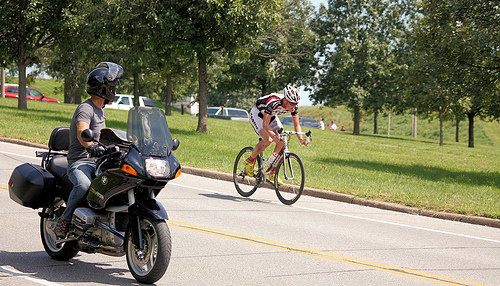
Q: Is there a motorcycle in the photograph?
A: Yes, there is a motorcycle.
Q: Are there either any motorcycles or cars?
A: Yes, there is a motorcycle.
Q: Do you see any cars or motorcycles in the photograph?
A: Yes, there is a motorcycle.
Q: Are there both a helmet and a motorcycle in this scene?
A: Yes, there are both a motorcycle and a helmet.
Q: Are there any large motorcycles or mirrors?
A: Yes, there is a large motorcycle.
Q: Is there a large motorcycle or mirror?
A: Yes, there is a large motorcycle.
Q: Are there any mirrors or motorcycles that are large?
A: Yes, the motorcycle is large.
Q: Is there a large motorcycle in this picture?
A: Yes, there is a large motorcycle.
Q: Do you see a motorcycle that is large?
A: Yes, there is a motorcycle that is large.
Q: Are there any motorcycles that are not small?
A: Yes, there is a large motorcycle.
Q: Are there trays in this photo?
A: No, there are no trays.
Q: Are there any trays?
A: No, there are no trays.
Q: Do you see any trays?
A: No, there are no trays.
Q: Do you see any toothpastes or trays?
A: No, there are no trays or toothpastes.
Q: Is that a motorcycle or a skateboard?
A: That is a motorcycle.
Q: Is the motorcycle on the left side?
A: Yes, the motorcycle is on the left of the image.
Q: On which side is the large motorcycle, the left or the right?
A: The motorcycle is on the left of the image.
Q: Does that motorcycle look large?
A: Yes, the motorcycle is large.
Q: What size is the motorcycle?
A: The motorcycle is large.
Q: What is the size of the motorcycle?
A: The motorcycle is large.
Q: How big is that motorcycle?
A: The motorcycle is large.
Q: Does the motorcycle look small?
A: No, the motorcycle is large.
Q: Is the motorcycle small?
A: No, the motorcycle is large.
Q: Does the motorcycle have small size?
A: No, the motorcycle is large.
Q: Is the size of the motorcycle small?
A: No, the motorcycle is large.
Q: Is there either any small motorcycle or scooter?
A: No, there is a motorcycle but it is large.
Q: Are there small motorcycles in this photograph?
A: No, there is a motorcycle but it is large.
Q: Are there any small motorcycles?
A: No, there is a motorcycle but it is large.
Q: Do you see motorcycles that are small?
A: No, there is a motorcycle but it is large.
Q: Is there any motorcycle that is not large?
A: No, there is a motorcycle but it is large.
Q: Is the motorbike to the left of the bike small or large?
A: The motorcycle is large.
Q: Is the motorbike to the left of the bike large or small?
A: The motorcycle is large.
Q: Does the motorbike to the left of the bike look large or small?
A: The motorcycle is large.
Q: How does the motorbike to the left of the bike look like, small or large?
A: The motorcycle is large.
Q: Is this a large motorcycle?
A: Yes, this is a large motorcycle.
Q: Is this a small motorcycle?
A: No, this is a large motorcycle.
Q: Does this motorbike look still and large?
A: Yes, the motorbike is still and large.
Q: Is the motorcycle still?
A: Yes, the motorcycle is still.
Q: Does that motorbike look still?
A: Yes, the motorbike is still.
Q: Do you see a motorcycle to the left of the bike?
A: Yes, there is a motorcycle to the left of the bike.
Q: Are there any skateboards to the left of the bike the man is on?
A: No, there is a motorcycle to the left of the bike.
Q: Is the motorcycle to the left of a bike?
A: Yes, the motorcycle is to the left of a bike.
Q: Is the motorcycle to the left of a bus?
A: No, the motorcycle is to the left of a bike.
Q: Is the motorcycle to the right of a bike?
A: No, the motorcycle is to the left of a bike.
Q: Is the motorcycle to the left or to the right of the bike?
A: The motorcycle is to the left of the bike.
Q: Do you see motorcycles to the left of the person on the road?
A: Yes, there is a motorcycle to the left of the person.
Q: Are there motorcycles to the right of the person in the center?
A: No, the motorcycle is to the left of the person.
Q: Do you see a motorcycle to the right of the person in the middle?
A: No, the motorcycle is to the left of the person.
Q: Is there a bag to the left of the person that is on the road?
A: No, there is a motorcycle to the left of the person.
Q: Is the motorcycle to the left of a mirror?
A: No, the motorcycle is to the left of the person.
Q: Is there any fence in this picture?
A: No, there are no fences.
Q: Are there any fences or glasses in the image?
A: No, there are no fences or glasses.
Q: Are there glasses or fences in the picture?
A: No, there are no fences or glasses.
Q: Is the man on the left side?
A: Yes, the man is on the left of the image.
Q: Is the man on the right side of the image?
A: No, the man is on the left of the image.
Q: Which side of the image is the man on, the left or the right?
A: The man is on the left of the image.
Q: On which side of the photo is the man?
A: The man is on the left of the image.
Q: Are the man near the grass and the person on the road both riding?
A: Yes, both the man and the person are riding.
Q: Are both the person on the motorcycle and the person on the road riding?
A: Yes, both the man and the person are riding.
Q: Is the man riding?
A: Yes, the man is riding.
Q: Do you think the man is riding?
A: Yes, the man is riding.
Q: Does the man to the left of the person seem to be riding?
A: Yes, the man is riding.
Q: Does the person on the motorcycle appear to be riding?
A: Yes, the man is riding.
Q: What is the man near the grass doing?
A: The man is riding.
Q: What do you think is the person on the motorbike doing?
A: The man is riding.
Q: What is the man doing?
A: The man is riding.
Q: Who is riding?
A: The man is riding.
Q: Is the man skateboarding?
A: No, the man is riding.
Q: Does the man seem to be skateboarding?
A: No, the man is riding.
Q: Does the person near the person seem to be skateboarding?
A: No, the man is riding.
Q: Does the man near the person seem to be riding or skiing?
A: The man is riding.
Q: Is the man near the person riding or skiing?
A: The man is riding.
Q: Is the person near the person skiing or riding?
A: The man is riding.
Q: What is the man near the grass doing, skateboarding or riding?
A: The man is riding.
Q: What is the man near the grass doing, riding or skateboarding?
A: The man is riding.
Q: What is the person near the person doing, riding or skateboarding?
A: The man is riding.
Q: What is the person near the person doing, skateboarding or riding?
A: The man is riding.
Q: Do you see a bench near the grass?
A: No, there is a man near the grass.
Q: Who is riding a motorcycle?
A: The man is riding a motorcycle.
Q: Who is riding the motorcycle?
A: The man is riding a motorcycle.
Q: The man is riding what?
A: The man is riding a motorcycle.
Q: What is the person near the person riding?
A: The man is riding a motorcycle.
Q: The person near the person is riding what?
A: The man is riding a motorcycle.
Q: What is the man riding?
A: The man is riding a motorcycle.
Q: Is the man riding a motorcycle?
A: Yes, the man is riding a motorcycle.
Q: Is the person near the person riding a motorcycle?
A: Yes, the man is riding a motorcycle.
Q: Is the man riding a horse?
A: No, the man is riding a motorcycle.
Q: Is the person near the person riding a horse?
A: No, the man is riding a motorcycle.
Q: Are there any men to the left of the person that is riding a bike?
A: Yes, there is a man to the left of the person.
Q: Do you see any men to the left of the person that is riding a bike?
A: Yes, there is a man to the left of the person.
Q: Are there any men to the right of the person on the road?
A: No, the man is to the left of the person.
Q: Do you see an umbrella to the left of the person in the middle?
A: No, there is a man to the left of the person.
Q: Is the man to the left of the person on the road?
A: Yes, the man is to the left of the person.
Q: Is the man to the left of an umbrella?
A: No, the man is to the left of the person.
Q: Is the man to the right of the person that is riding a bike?
A: No, the man is to the left of the person.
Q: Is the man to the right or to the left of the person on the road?
A: The man is to the left of the person.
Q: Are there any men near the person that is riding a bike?
A: Yes, there is a man near the person.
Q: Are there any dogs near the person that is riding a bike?
A: No, there is a man near the person.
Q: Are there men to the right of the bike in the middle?
A: No, the man is to the left of the bike.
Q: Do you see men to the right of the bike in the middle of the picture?
A: No, the man is to the left of the bike.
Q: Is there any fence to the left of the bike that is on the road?
A: No, there is a man to the left of the bike.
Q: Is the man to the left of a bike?
A: Yes, the man is to the left of a bike.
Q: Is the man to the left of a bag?
A: No, the man is to the left of a bike.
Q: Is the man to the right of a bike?
A: No, the man is to the left of a bike.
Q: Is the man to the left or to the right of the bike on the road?
A: The man is to the left of the bike.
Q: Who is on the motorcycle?
A: The man is on the motorcycle.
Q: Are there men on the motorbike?
A: Yes, there is a man on the motorbike.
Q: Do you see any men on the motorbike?
A: Yes, there is a man on the motorbike.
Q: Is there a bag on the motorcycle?
A: No, there is a man on the motorcycle.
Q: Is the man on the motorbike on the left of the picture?
A: Yes, the man is on the motorbike.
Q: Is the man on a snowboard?
A: No, the man is on the motorbike.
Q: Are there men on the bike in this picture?
A: Yes, there is a man on the bike.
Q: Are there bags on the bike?
A: No, there is a man on the bike.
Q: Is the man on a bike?
A: Yes, the man is on a bike.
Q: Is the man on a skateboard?
A: No, the man is on a bike.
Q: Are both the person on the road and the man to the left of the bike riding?
A: Yes, both the person and the man are riding.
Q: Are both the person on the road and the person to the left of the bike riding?
A: Yes, both the person and the man are riding.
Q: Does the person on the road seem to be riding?
A: Yes, the person is riding.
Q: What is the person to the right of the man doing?
A: The person is riding.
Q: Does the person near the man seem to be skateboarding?
A: No, the person is riding.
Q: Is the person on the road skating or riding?
A: The person is riding.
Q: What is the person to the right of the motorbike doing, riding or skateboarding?
A: The person is riding.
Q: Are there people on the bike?
A: Yes, there is a person on the bike.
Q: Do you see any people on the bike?
A: Yes, there is a person on the bike.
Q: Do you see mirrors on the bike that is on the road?
A: No, there is a person on the bike.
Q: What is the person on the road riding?
A: The person is riding a bike.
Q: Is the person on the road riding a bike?
A: Yes, the person is riding a bike.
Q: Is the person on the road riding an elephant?
A: No, the person is riding a bike.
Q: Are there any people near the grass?
A: Yes, there is a person near the grass.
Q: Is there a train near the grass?
A: No, there is a person near the grass.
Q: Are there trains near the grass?
A: No, there is a person near the grass.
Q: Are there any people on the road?
A: Yes, there is a person on the road.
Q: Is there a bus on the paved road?
A: No, there is a person on the road.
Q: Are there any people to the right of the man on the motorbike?
A: Yes, there is a person to the right of the man.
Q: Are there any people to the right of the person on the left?
A: Yes, there is a person to the right of the man.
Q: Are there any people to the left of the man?
A: No, the person is to the right of the man.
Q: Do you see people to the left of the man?
A: No, the person is to the right of the man.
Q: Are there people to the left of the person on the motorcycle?
A: No, the person is to the right of the man.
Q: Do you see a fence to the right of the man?
A: No, there is a person to the right of the man.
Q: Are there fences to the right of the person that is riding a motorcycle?
A: No, there is a person to the right of the man.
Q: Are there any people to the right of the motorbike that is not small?
A: Yes, there is a person to the right of the motorbike.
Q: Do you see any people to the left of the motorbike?
A: No, the person is to the right of the motorbike.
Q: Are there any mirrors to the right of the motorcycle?
A: No, there is a person to the right of the motorcycle.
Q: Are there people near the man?
A: Yes, there is a person near the man.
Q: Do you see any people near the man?
A: Yes, there is a person near the man.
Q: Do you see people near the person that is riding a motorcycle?
A: Yes, there is a person near the man.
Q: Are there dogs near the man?
A: No, there is a person near the man.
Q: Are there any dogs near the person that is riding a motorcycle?
A: No, there is a person near the man.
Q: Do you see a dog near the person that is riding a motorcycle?
A: No, there is a person near the man.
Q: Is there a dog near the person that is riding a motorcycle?
A: No, there is a person near the man.